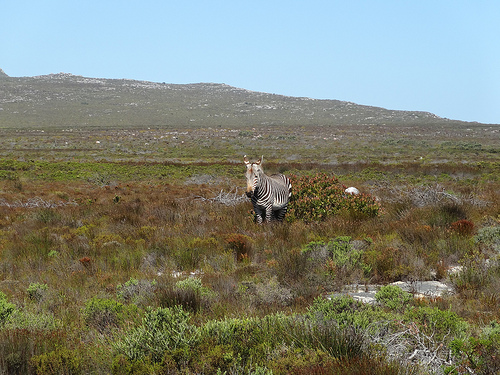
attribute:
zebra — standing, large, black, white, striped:
[239, 152, 298, 224]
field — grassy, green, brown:
[1, 156, 498, 374]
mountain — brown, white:
[1, 73, 466, 130]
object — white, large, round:
[344, 185, 362, 195]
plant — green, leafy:
[171, 269, 206, 308]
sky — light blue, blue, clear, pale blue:
[1, 0, 500, 124]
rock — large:
[342, 278, 456, 305]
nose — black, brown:
[245, 187, 256, 199]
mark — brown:
[248, 162, 254, 178]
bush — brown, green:
[277, 168, 380, 223]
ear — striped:
[241, 153, 250, 168]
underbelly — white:
[272, 201, 285, 213]